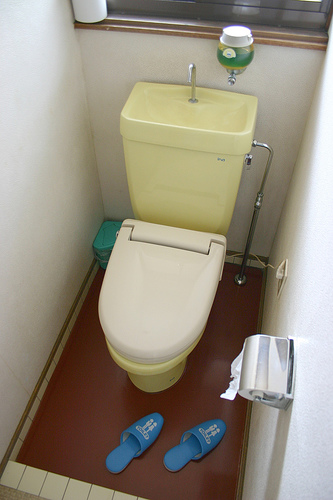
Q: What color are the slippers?
A: Blue and white.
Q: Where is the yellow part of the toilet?
A: Basin.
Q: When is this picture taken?
A: Day time.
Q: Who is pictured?
A: No one.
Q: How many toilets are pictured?
A: One.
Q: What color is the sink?
A: Yellow.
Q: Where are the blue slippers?
A: Front of toilet.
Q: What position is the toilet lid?
A: Closed.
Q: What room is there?
A: Bathroom.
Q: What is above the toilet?
A: Window.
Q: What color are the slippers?
A: Blue.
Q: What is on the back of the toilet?
A: Sink.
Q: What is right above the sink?
A: Soap dispenser.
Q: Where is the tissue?
A: Window seal.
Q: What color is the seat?
A: White.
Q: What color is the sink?
A: Yellow.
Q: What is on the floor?
A: Slippers.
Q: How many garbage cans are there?
A: One.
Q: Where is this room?
A: Bathroom.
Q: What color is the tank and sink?
A: Yellow.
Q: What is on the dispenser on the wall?
A: Toilet paper.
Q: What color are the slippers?
A: Blue.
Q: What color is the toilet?
A: Yellow and white.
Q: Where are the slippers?
A: The floor.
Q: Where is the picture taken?
A: Bathroom.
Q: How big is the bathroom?
A: Small.